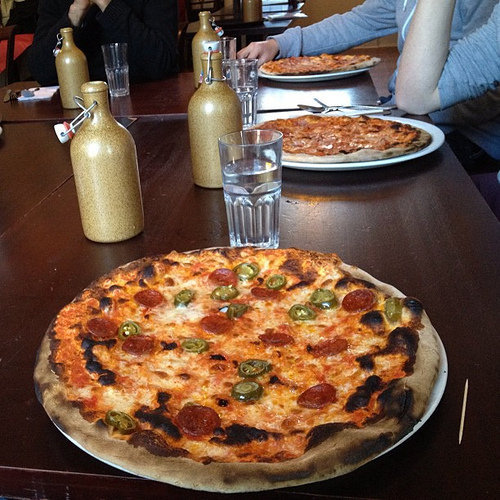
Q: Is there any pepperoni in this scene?
A: Yes, there is pepperoni.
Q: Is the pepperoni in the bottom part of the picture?
A: Yes, the pepperoni is in the bottom of the image.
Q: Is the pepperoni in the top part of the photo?
A: No, the pepperoni is in the bottom of the image.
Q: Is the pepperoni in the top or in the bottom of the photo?
A: The pepperoni is in the bottom of the image.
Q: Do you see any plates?
A: Yes, there is a plate.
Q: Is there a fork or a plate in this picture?
A: Yes, there is a plate.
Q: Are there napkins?
A: No, there are no napkins.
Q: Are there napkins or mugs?
A: No, there are no napkins or mugs.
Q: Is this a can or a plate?
A: This is a plate.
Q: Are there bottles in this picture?
A: Yes, there is a bottle.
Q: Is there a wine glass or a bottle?
A: Yes, there is a bottle.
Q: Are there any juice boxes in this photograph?
A: No, there are no juice boxes.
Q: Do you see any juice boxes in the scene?
A: No, there are no juice boxes.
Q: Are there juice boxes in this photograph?
A: No, there are no juice boxes.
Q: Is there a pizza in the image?
A: Yes, there is a pizza.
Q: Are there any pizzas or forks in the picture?
A: Yes, there is a pizza.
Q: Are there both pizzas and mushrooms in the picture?
A: No, there is a pizza but no mushrooms.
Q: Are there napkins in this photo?
A: No, there are no napkins.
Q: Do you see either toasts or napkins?
A: No, there are no napkins or toasts.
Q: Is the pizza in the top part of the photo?
A: Yes, the pizza is in the top of the image.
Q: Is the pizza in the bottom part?
A: No, the pizza is in the top of the image.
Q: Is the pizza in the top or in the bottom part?
A: The pizza is in the top of the image.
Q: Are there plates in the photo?
A: Yes, there is a plate.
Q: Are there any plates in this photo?
A: Yes, there is a plate.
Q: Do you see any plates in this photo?
A: Yes, there is a plate.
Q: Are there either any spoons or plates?
A: Yes, there is a plate.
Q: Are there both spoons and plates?
A: No, there is a plate but no spoons.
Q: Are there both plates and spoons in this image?
A: No, there is a plate but no spoons.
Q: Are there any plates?
A: Yes, there is a plate.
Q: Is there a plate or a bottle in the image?
A: Yes, there is a plate.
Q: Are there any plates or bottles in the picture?
A: Yes, there is a plate.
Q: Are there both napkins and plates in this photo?
A: No, there is a plate but no napkins.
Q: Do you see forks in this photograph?
A: Yes, there is a fork.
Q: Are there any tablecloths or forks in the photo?
A: Yes, there is a fork.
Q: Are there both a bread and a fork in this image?
A: No, there is a fork but no breads.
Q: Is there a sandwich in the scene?
A: No, there are no sandwiches.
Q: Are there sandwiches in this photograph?
A: No, there are no sandwiches.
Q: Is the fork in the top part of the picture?
A: Yes, the fork is in the top of the image.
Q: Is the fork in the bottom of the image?
A: No, the fork is in the top of the image.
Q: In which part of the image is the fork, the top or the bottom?
A: The fork is in the top of the image.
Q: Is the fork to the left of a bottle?
A: No, the fork is to the right of a bottle.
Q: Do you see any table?
A: Yes, there is a table.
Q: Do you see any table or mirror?
A: Yes, there is a table.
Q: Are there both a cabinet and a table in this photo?
A: No, there is a table but no cabinets.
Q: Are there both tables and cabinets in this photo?
A: No, there is a table but no cabinets.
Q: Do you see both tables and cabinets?
A: No, there is a table but no cabinets.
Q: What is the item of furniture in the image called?
A: The piece of furniture is a table.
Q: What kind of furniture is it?
A: The piece of furniture is a table.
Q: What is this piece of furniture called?
A: This is a table.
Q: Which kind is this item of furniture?
A: This is a table.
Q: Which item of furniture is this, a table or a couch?
A: This is a table.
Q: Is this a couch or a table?
A: This is a table.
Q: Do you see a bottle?
A: Yes, there is a bottle.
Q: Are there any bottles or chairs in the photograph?
A: Yes, there is a bottle.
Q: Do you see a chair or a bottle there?
A: Yes, there is a bottle.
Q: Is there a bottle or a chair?
A: Yes, there is a bottle.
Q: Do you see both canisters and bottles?
A: No, there is a bottle but no canisters.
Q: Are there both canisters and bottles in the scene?
A: No, there is a bottle but no canisters.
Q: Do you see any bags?
A: No, there are no bags.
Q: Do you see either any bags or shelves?
A: No, there are no bags or shelves.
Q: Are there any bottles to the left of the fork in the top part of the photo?
A: Yes, there is a bottle to the left of the fork.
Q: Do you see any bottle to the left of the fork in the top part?
A: Yes, there is a bottle to the left of the fork.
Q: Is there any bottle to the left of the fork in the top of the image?
A: Yes, there is a bottle to the left of the fork.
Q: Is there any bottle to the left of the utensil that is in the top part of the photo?
A: Yes, there is a bottle to the left of the fork.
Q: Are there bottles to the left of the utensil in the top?
A: Yes, there is a bottle to the left of the fork.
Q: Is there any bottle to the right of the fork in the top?
A: No, the bottle is to the left of the fork.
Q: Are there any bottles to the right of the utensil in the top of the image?
A: No, the bottle is to the left of the fork.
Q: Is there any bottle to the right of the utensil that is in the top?
A: No, the bottle is to the left of the fork.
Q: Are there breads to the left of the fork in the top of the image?
A: No, there is a bottle to the left of the fork.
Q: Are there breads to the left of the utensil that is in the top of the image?
A: No, there is a bottle to the left of the fork.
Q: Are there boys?
A: No, there are no boys.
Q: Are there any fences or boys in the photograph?
A: No, there are no boys or fences.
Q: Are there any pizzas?
A: Yes, there is a pizza.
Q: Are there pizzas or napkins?
A: Yes, there is a pizza.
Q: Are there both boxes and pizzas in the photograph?
A: No, there is a pizza but no boxes.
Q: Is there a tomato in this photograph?
A: No, there are no tomatoes.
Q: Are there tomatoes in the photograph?
A: No, there are no tomatoes.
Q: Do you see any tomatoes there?
A: No, there are no tomatoes.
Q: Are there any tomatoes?
A: No, there are no tomatoes.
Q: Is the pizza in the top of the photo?
A: Yes, the pizza is in the top of the image.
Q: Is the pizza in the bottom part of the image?
A: No, the pizza is in the top of the image.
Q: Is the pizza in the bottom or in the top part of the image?
A: The pizza is in the top of the image.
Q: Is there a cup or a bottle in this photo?
A: Yes, there is a bottle.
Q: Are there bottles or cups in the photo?
A: Yes, there is a bottle.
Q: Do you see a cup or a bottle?
A: Yes, there is a bottle.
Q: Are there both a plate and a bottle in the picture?
A: Yes, there are both a bottle and a plate.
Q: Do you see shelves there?
A: No, there are no shelves.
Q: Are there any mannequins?
A: No, there are no mannequins.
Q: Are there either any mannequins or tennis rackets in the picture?
A: No, there are no mannequins or tennis rackets.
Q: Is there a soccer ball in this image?
A: No, there are no soccer balls.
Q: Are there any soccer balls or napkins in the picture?
A: No, there are no soccer balls or napkins.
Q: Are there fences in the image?
A: No, there are no fences.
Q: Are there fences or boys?
A: No, there are no fences or boys.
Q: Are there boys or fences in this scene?
A: No, there are no fences or boys.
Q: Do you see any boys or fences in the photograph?
A: No, there are no fences or boys.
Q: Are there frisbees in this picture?
A: No, there are no frisbees.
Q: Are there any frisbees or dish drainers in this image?
A: No, there are no frisbees or dish drainers.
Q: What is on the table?
A: The glass is on the table.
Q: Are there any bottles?
A: Yes, there is a bottle.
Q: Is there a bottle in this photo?
A: Yes, there is a bottle.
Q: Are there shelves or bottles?
A: Yes, there is a bottle.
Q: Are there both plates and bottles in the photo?
A: Yes, there are both a bottle and a plate.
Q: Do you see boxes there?
A: No, there are no boxes.